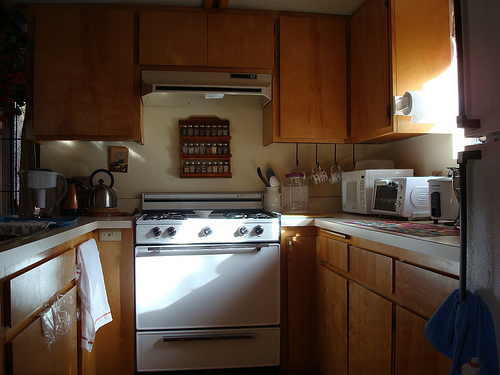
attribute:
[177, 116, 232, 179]
shelf — wooden, brown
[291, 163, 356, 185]
mugs — hanging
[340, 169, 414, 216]
microwave — white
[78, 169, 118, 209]
kettle — stainless steel, silver, black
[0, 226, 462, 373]
cabinets — brown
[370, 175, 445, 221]
toaster oven — white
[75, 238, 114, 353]
dish towel — white, hanging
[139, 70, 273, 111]
range — white, electric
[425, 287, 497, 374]
towel — blue